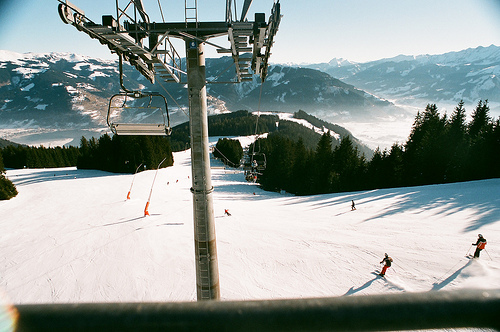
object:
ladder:
[180, 0, 214, 300]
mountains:
[298, 43, 498, 106]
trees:
[327, 134, 363, 194]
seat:
[105, 55, 173, 139]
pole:
[0, 286, 499, 331]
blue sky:
[0, 0, 498, 66]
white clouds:
[0, 0, 499, 66]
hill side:
[0, 178, 499, 332]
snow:
[0, 176, 499, 332]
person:
[248, 158, 260, 174]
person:
[347, 199, 356, 211]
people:
[376, 252, 395, 278]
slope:
[0, 121, 499, 331]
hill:
[0, 117, 499, 332]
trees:
[294, 129, 336, 199]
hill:
[0, 50, 415, 129]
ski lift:
[247, 151, 267, 173]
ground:
[0, 109, 499, 331]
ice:
[0, 106, 499, 305]